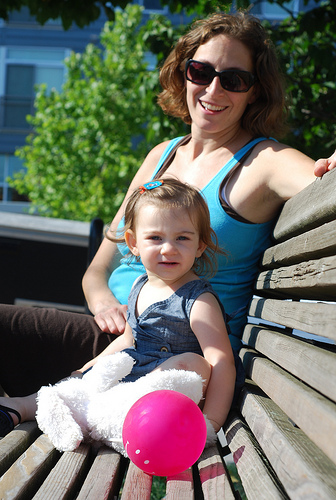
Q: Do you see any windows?
A: Yes, there is a window.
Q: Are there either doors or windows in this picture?
A: Yes, there is a window.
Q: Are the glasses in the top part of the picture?
A: Yes, the glasses are in the top of the image.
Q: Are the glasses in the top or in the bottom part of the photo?
A: The glasses are in the top of the image.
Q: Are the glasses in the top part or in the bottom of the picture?
A: The glasses are in the top of the image.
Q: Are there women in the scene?
A: Yes, there is a woman.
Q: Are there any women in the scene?
A: Yes, there is a woman.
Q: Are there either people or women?
A: Yes, there is a woman.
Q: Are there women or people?
A: Yes, there is a woman.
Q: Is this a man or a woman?
A: This is a woman.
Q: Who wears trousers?
A: The woman wears trousers.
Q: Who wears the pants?
A: The woman wears trousers.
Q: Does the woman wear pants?
A: Yes, the woman wears pants.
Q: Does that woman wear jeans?
A: No, the woman wears pants.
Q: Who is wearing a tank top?
A: The woman is wearing a tank top.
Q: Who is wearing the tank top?
A: The woman is wearing a tank top.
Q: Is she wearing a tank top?
A: Yes, the woman is wearing a tank top.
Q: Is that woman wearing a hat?
A: No, the woman is wearing a tank top.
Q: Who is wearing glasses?
A: The woman is wearing glasses.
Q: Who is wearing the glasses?
A: The woman is wearing glasses.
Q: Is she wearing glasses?
A: Yes, the woman is wearing glasses.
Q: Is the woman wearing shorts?
A: No, the woman is wearing glasses.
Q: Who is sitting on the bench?
A: The woman is sitting on the bench.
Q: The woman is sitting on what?
A: The woman is sitting on the bench.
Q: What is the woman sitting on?
A: The woman is sitting on the bench.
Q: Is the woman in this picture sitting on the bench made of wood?
A: Yes, the woman is sitting on the bench.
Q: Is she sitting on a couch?
A: No, the woman is sitting on the bench.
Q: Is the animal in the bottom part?
A: Yes, the animal is in the bottom of the image.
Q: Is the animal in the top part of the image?
A: No, the animal is in the bottom of the image.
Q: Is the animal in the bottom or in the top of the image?
A: The animal is in the bottom of the image.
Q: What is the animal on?
A: The animal is on the bench.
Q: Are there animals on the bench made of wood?
A: Yes, there is an animal on the bench.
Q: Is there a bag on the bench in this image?
A: No, there is an animal on the bench.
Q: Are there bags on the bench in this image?
A: No, there is an animal on the bench.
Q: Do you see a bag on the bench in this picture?
A: No, there is an animal on the bench.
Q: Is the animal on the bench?
A: Yes, the animal is on the bench.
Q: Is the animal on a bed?
A: No, the animal is on the bench.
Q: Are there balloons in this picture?
A: Yes, there is a balloon.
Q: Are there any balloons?
A: Yes, there is a balloon.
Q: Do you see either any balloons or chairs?
A: Yes, there is a balloon.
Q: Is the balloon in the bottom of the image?
A: Yes, the balloon is in the bottom of the image.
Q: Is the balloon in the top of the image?
A: No, the balloon is in the bottom of the image.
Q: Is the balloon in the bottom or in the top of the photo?
A: The balloon is in the bottom of the image.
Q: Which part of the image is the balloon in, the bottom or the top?
A: The balloon is in the bottom of the image.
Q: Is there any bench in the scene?
A: Yes, there is a bench.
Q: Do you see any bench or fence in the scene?
A: Yes, there is a bench.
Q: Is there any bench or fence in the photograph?
A: Yes, there is a bench.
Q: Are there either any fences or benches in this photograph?
A: Yes, there is a bench.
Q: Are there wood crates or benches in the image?
A: Yes, there is a wood bench.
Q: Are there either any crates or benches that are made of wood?
A: Yes, the bench is made of wood.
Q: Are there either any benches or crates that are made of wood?
A: Yes, the bench is made of wood.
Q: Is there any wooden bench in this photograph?
A: Yes, there is a wood bench.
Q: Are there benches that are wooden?
A: Yes, there is a bench that is wooden.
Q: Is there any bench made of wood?
A: Yes, there is a bench that is made of wood.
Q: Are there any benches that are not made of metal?
A: Yes, there is a bench that is made of wood.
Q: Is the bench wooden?
A: Yes, the bench is wooden.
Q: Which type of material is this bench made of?
A: The bench is made of wood.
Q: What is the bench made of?
A: The bench is made of wood.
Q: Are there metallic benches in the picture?
A: No, there is a bench but it is wooden.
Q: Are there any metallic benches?
A: No, there is a bench but it is wooden.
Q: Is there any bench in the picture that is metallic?
A: No, there is a bench but it is wooden.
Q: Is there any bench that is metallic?
A: No, there is a bench but it is wooden.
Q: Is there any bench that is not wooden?
A: No, there is a bench but it is wooden.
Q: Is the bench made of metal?
A: No, the bench is made of wood.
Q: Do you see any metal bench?
A: No, there is a bench but it is made of wood.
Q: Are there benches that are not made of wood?
A: No, there is a bench but it is made of wood.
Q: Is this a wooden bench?
A: Yes, this is a wooden bench.